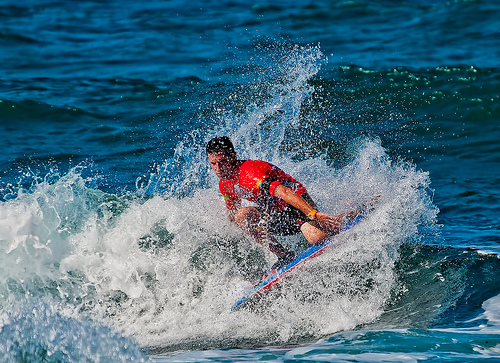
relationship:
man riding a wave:
[205, 136, 341, 274] [27, 188, 262, 317]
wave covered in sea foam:
[27, 188, 262, 317] [7, 39, 212, 299]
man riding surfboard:
[205, 136, 341, 274] [229, 185, 420, 313]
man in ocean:
[205, 136, 341, 274] [0, 1, 498, 361]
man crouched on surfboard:
[205, 136, 341, 274] [221, 203, 383, 319]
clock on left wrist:
[303, 212, 313, 224] [306, 208, 321, 221]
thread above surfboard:
[253, 216, 277, 281] [221, 203, 383, 319]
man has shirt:
[205, 136, 341, 274] [209, 154, 298, 204]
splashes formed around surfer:
[99, 222, 206, 307] [191, 127, 355, 264]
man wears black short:
[205, 136, 341, 274] [256, 190, 318, 236]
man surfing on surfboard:
[205, 136, 341, 274] [229, 171, 428, 311]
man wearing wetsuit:
[205, 136, 341, 274] [215, 158, 320, 238]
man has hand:
[205, 136, 341, 274] [303, 205, 345, 232]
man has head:
[205, 130, 342, 274] [205, 136, 236, 181]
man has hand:
[205, 136, 341, 274] [313, 210, 343, 231]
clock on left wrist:
[307, 209, 318, 220] [303, 202, 321, 215]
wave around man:
[27, 188, 262, 317] [205, 136, 341, 274]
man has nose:
[205, 136, 341, 274] [214, 160, 221, 169]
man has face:
[205, 136, 341, 274] [208, 153, 236, 178]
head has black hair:
[201, 134, 238, 185] [204, 132, 236, 159]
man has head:
[205, 136, 341, 274] [201, 134, 238, 185]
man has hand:
[205, 130, 342, 274] [315, 211, 344, 232]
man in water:
[205, 130, 342, 274] [1, 0, 498, 360]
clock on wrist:
[307, 209, 318, 220] [303, 210, 318, 220]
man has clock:
[205, 130, 342, 274] [307, 209, 318, 220]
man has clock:
[205, 136, 341, 274] [307, 209, 318, 220]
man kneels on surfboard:
[205, 136, 341, 274] [232, 192, 380, 319]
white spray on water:
[175, 41, 329, 152] [1, 0, 498, 360]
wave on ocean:
[27, 188, 262, 317] [0, 1, 498, 361]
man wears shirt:
[205, 136, 341, 274] [218, 158, 307, 210]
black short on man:
[256, 190, 311, 235] [205, 136, 341, 274]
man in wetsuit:
[205, 136, 341, 274] [209, 155, 324, 240]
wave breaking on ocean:
[27, 188, 262, 317] [0, 1, 498, 361]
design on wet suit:
[230, 185, 254, 205] [213, 157, 320, 237]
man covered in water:
[205, 136, 341, 274] [1, 0, 498, 360]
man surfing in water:
[205, 136, 341, 274] [1, 0, 498, 360]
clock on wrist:
[307, 209, 318, 220] [307, 203, 321, 224]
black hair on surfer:
[206, 136, 236, 159] [153, 95, 418, 331]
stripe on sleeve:
[259, 169, 278, 193] [256, 174, 282, 198]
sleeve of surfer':
[256, 174, 282, 198] [182, 137, 354, 281]